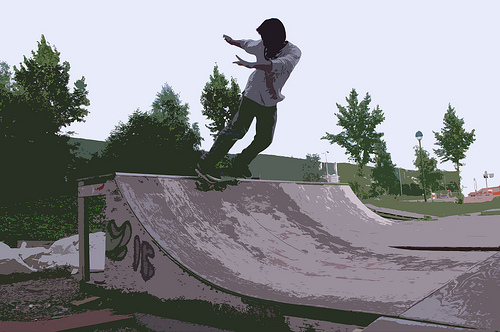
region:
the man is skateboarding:
[197, 19, 334, 215]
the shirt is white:
[234, 40, 290, 100]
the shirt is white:
[227, 28, 311, 118]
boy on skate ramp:
[188, 12, 304, 195]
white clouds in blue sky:
[418, 28, 481, 63]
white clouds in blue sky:
[358, 29, 389, 53]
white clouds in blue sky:
[410, 7, 463, 55]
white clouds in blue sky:
[61, 12, 137, 54]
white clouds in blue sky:
[141, 8, 217, 76]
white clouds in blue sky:
[322, 11, 362, 43]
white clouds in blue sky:
[287, 68, 350, 100]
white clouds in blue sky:
[379, 24, 430, 68]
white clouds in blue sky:
[348, 47, 418, 105]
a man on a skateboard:
[193, 16, 300, 187]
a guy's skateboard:
[193, 167, 237, 185]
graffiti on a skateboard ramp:
[105, 218, 155, 280]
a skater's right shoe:
[196, 160, 226, 182]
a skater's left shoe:
[230, 155, 253, 179]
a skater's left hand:
[230, 53, 257, 70]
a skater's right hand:
[222, 34, 235, 44]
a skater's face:
[256, 17, 285, 50]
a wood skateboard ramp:
[75, 173, 496, 328]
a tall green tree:
[433, 104, 475, 190]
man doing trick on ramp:
[225, 7, 296, 187]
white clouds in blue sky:
[64, 1, 92, 31]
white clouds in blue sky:
[390, 59, 435, 99]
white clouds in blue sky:
[382, 20, 411, 55]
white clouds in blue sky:
[443, 24, 478, 67]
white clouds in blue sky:
[332, 26, 367, 61]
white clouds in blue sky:
[157, 3, 202, 37]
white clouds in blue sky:
[94, 32, 132, 56]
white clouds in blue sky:
[99, 13, 138, 53]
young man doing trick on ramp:
[171, 6, 318, 185]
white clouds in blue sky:
[71, 20, 100, 72]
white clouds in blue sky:
[354, 40, 401, 76]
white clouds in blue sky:
[400, 24, 452, 57]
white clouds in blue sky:
[285, 77, 326, 105]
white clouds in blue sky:
[149, 15, 172, 44]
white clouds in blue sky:
[98, 37, 138, 64]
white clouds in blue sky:
[73, 3, 127, 41]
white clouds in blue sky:
[103, 56, 145, 79]